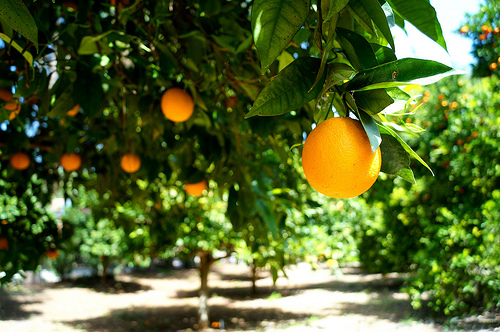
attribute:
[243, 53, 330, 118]
tree leaf — dark green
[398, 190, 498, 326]
tree — green, leafy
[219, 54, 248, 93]
tree limb — brown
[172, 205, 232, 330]
tree — gray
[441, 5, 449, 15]
sky — blue, clear